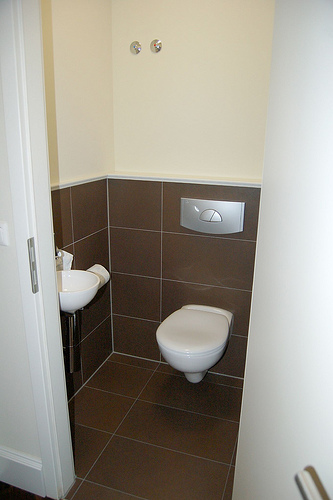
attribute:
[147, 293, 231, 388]
procelain toilet — white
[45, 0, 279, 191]
wall — bathroom, beige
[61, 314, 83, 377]
pipe — drain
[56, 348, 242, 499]
floor — brown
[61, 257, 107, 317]
sink — bowl like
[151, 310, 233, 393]
toilet — white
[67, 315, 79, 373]
pipe — silver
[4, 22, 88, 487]
doorway — white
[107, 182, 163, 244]
tile — brown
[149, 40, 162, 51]
knob — red, green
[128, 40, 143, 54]
knob — red, green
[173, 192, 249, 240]
dispenser — silver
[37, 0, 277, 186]
upper wall — tan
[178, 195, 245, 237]
dispenser — silver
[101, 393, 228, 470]
floor — brown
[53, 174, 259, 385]
wall — brown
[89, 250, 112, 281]
toilet tissue — white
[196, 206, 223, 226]
button — gray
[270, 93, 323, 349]
white — bathroom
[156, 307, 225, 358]
toilet seat — white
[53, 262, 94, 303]
sink — white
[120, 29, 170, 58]
buttons — red, blue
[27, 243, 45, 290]
handle — chrome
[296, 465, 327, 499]
bar — white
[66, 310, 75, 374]
pipe — silver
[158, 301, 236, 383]
toilet — white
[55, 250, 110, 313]
urinal — white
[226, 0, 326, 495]
door — white